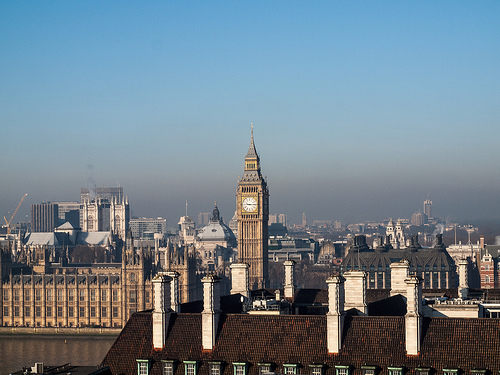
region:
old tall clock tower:
[234, 120, 266, 290]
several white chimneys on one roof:
[148, 257, 422, 359]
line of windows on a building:
[134, 358, 487, 373]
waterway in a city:
[1, 331, 121, 369]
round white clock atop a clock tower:
[241, 196, 258, 212]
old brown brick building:
[1, 239, 189, 336]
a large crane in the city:
[1, 190, 29, 230]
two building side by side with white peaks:
[79, 193, 129, 239]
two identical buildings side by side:
[383, 215, 408, 250]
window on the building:
[136, 359, 147, 374]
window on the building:
[161, 362, 175, 374]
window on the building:
[185, 360, 196, 374]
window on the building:
[208, 363, 220, 374]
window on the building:
[233, 363, 245, 373]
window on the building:
[283, 363, 298, 374]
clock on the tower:
[237, 192, 263, 212]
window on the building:
[78, 287, 84, 299]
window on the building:
[88, 306, 96, 316]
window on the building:
[103, 306, 106, 318]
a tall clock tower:
[236, 125, 271, 296]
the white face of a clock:
[241, 195, 258, 214]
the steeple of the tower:
[247, 120, 261, 167]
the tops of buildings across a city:
[2, 204, 498, 319]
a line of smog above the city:
[9, 156, 495, 226]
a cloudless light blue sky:
[0, 2, 493, 159]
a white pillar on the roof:
[320, 275, 347, 357]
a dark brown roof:
[112, 314, 497, 371]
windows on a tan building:
[3, 289, 122, 327]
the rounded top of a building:
[196, 217, 238, 238]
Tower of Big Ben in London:
[234, 126, 268, 289]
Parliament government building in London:
[5, 230, 222, 329]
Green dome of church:
[195, 205, 231, 238]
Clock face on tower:
[239, 196, 259, 213]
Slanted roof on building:
[102, 319, 497, 367]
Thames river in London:
[3, 333, 117, 373]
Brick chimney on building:
[341, 270, 368, 312]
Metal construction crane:
[2, 187, 29, 236]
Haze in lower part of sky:
[12, 171, 499, 234]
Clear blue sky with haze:
[3, 5, 499, 227]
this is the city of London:
[9, 61, 491, 372]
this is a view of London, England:
[6, 9, 481, 372]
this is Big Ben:
[225, 95, 290, 325]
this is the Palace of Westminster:
[1, 100, 302, 371]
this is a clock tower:
[218, 105, 294, 323]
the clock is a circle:
[231, 182, 267, 223]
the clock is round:
[233, 192, 258, 215]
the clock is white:
[235, 187, 258, 214]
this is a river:
[2, 335, 128, 370]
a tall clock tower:
[233, 110, 295, 320]